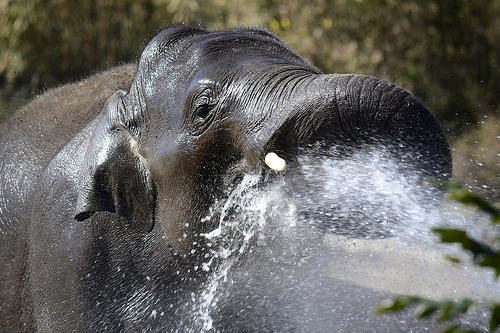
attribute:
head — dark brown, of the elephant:
[78, 17, 458, 252]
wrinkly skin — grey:
[157, 27, 416, 167]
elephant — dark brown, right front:
[6, 15, 451, 327]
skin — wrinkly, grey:
[99, 79, 169, 136]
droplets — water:
[262, 241, 342, 318]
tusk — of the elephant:
[266, 150, 287, 174]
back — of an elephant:
[0, 58, 186, 210]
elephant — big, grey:
[5, 17, 498, 329]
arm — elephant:
[29, 250, 151, 332]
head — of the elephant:
[134, 30, 324, 236]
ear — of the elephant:
[60, 108, 175, 258]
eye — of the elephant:
[192, 103, 213, 118]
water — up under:
[216, 126, 372, 288]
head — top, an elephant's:
[57, 20, 418, 220]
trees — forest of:
[0, 1, 495, 140]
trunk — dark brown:
[298, 66, 456, 259]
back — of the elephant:
[20, 53, 144, 105]